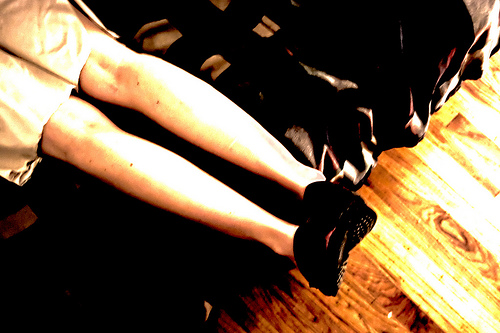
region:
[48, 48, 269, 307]
a pair of legs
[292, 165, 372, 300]
black shoes on the person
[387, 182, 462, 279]
light brown floor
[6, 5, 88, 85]
white shorts on the person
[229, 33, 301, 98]
black blanket on the bed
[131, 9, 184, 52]
brown patch on the bed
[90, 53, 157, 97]
knee on the person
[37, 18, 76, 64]
wrinkles on the shorts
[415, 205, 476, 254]
knots on the wooden floor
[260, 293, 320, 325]
dark brown on the floor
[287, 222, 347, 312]
The left dark shoe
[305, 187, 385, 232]
The right dark shoe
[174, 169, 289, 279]
A portion of the boy's right leg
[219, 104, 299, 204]
A portion of the boy's left leg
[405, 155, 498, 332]
A wooden plank board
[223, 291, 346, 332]
Another portion of wood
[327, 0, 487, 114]
The uppermost portion of the bed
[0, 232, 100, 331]
The lowermost portion of the bed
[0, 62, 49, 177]
The right shorts leg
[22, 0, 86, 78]
The left shorts leg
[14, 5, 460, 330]
legs laying down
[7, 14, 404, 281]
legs laying on a bed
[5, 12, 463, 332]
legs resting on a bed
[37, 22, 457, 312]
white legs that are resting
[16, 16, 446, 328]
white legs next to each other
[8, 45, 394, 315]
legs that are resting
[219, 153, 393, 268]
a pair of shoes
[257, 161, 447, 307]
a pair of black shoes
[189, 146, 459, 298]
a pair of shoes on feet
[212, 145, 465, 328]
a pair of black shoes on feet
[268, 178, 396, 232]
Right Black Slipper On Foot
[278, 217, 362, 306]
Left Black Slipper On Foot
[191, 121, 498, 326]
Naturally Stained Wooden Floor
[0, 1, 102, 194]
Tan Above Knee Shorts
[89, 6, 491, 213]
Dark Plaid With White Comforter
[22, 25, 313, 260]
Shaved Pale Skin Legs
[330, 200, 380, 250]
Black Bottom of Slipper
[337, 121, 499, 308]
Sunlight on wooden floor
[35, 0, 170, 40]
Shorts String Tie Untied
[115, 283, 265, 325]
Things Underneath the bed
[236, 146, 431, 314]
Black shoes on the person.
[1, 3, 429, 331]
Person sitting on a couch.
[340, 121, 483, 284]
Wood floor on the ground.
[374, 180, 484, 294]
Wood grain on the floor.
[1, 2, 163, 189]
Shirts on the man.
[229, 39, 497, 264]
couch on the wood floor.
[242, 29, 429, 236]
Blanket on the couch.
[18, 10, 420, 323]
Person's bare legs on the couch.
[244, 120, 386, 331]
Black shoes on someone's feet.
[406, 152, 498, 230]
Light on the wood floor